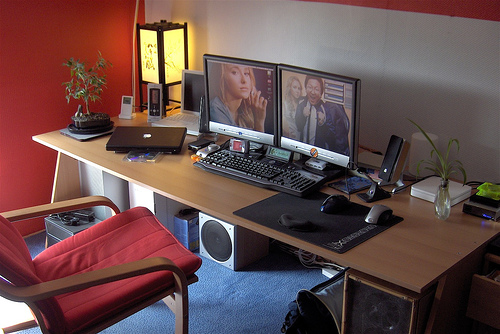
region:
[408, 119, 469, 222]
Small plant in a clear vase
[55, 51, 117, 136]
Small plant in a black vase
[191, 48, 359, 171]
Two computer screens, both on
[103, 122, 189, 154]
Closed Apple laptop computer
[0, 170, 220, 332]
Red chair with a wooden frame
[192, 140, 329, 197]
Black keyboard for a computer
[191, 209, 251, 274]
Silver and black subwoofer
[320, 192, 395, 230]
Two mice for computers on a black mouse pad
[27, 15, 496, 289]
Desk with multiple computers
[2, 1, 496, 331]
Home work station with multiple computers and comfortable chair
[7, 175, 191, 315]
the office chair has wooden handles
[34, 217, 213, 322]
the red wooden chair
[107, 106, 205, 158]
the black laptop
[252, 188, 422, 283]
the black mousepad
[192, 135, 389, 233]
the black keyboard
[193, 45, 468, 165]
two computer monitors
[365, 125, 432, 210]
black computer speaker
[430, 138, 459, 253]
glass vase with a plant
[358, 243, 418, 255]
the desk was made of wood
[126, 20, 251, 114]
a lamp is in the corner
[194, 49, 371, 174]
Two monitors next to each other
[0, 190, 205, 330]
Red computer wooden chair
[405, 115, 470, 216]
Vase with plant on wooden table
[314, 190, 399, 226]
Set of two computer mouses on desk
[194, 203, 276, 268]
Speaker system underneath table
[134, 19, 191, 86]
Yellow lamp shinning brightly in room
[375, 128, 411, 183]
Right computer speaker facing monitor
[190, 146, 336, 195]
Black computer keyboard at monitor base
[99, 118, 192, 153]
Closed laptop on table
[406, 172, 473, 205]
White internet router on table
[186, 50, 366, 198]
a computer set up.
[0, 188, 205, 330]
a seat in front of a desk.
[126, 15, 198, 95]
a light on top of a desk.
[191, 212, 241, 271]
a speaker under a desk.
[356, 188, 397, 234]
a computer mouse on a desk.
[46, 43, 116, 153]
a plant in a vase on a table.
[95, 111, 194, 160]
A laptop on a desk.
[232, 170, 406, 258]
a giant mouse pad.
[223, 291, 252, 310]
a section of a blue floor.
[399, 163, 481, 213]
a white electronic device.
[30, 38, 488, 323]
a computer desk in a room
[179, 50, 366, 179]
this computer has a double screen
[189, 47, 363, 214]
a double monitor computer desk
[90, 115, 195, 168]
a laptop on the desk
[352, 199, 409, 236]
a mouse on the desk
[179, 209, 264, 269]
a speaker under the desk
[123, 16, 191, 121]
a light on the table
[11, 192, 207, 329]
a red chair next to a computer screen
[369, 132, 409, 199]
a speaker near a computer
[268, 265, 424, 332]
items around the computer desk